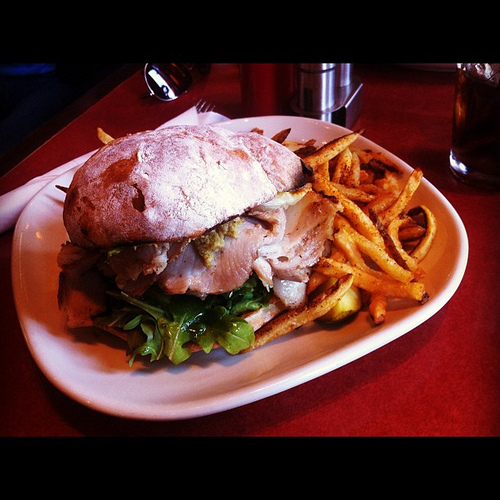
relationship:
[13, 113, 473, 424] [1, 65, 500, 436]
plate on top of table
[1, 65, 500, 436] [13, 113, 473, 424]
table under plate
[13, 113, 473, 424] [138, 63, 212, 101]
plate near glasses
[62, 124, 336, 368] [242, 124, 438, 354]
sandwich next to french fries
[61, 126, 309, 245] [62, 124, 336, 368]
roll on top of sandwich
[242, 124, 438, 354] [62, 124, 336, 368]
french fries next to sandwich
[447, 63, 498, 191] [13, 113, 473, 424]
coke next to plate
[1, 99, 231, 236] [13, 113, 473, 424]
silverware behind plate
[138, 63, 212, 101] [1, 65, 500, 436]
glasses on top of table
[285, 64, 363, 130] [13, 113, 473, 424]
salt and pepper shak behind plate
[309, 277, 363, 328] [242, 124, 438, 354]
pickle under french fries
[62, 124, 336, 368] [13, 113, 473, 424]
sandwich on plate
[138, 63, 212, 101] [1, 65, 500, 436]
glasses laying on table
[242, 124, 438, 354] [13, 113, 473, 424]
french fries on top of plate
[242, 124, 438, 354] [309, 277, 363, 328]
french fries on top of pickle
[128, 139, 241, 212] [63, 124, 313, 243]
powder on top of bread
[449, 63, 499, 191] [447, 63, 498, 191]
glass filled with coke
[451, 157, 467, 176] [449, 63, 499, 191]
light show on glass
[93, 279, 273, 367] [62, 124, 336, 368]
lettuce inside of sandwich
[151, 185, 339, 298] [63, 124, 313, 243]
pork under bread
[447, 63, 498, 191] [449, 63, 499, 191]
coke inside of glass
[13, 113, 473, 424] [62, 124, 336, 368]
plate under sandwich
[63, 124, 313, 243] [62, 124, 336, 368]
bread part of sandwich